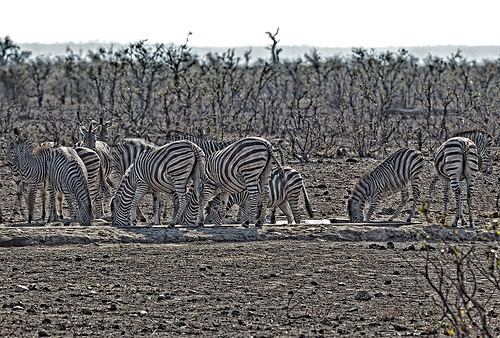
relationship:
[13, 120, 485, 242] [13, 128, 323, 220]
group of zebras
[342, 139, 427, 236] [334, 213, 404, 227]
zebra drinking water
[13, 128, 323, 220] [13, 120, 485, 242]
zebras in herd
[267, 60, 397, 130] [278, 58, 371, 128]
section of shrubbery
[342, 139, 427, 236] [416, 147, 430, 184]
zebra has tail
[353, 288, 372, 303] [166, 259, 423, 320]
rock on ground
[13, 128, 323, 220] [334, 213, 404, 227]
zebras drinking water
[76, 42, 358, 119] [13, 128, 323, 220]
trees behind zebras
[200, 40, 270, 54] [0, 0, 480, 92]
hills in background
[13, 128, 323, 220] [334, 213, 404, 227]
zebras at water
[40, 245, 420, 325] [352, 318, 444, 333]
dirt between photographer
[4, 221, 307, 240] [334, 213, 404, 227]
rocks around water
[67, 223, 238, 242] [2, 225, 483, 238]
stones form enclosure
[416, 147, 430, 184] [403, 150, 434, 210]
tail to side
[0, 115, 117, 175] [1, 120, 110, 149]
zebras with heads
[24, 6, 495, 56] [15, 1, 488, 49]
mountains at horizon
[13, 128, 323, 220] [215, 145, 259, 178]
zebras with stripes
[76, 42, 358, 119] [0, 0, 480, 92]
trees in background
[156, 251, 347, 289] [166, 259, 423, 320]
rocks on ground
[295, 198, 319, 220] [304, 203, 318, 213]
hair on tip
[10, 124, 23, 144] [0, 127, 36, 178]
fur on head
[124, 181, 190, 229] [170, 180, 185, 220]
legs have stripes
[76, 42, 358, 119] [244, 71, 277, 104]
trees without leaves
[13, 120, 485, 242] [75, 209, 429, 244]
herd at hole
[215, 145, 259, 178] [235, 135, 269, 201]
stripes on legs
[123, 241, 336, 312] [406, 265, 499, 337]
soil lacks vegetation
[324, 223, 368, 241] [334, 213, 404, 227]
edge of water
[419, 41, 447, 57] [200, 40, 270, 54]
row of hills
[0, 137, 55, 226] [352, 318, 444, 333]
zebra watching photographer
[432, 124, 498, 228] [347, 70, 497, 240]
zebra watches right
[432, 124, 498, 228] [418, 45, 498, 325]
zebra looking right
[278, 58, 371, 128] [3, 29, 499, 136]
branches without vegetation